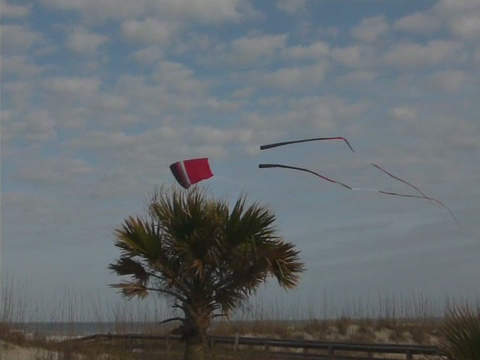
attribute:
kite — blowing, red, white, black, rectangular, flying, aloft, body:
[155, 143, 235, 196]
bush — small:
[427, 315, 479, 356]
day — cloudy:
[90, 28, 421, 103]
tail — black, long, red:
[259, 140, 381, 180]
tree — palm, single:
[132, 216, 283, 339]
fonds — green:
[220, 214, 290, 270]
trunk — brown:
[182, 316, 211, 359]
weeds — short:
[129, 326, 229, 359]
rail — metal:
[222, 335, 440, 360]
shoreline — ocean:
[62, 317, 360, 335]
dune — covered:
[307, 330, 436, 344]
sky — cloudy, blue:
[20, 39, 439, 193]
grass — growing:
[42, 320, 474, 360]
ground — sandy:
[240, 309, 479, 345]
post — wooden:
[57, 325, 140, 345]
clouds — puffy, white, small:
[118, 74, 247, 146]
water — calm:
[34, 311, 129, 332]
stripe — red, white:
[179, 162, 190, 185]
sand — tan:
[9, 341, 56, 359]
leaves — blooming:
[144, 233, 180, 282]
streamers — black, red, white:
[314, 147, 443, 225]